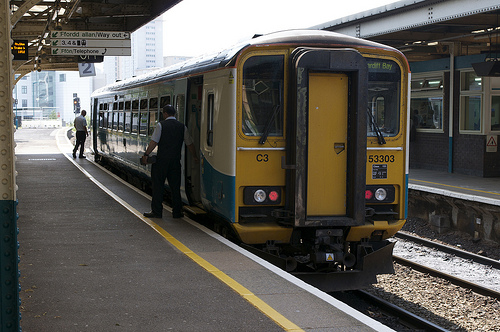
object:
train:
[90, 30, 407, 240]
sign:
[48, 24, 131, 55]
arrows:
[51, 31, 59, 39]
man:
[142, 103, 187, 225]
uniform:
[146, 119, 184, 222]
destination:
[363, 56, 398, 75]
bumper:
[262, 226, 398, 294]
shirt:
[160, 118, 183, 158]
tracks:
[345, 281, 443, 330]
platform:
[11, 3, 496, 331]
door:
[308, 70, 353, 218]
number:
[365, 154, 391, 162]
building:
[0, 0, 176, 331]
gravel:
[416, 279, 458, 305]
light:
[266, 188, 280, 201]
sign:
[252, 152, 271, 162]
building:
[29, 68, 57, 125]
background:
[12, 0, 219, 117]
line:
[179, 239, 221, 278]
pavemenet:
[20, 123, 230, 331]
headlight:
[251, 188, 266, 202]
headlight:
[376, 188, 386, 201]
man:
[74, 109, 89, 160]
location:
[58, 46, 107, 55]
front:
[236, 37, 401, 244]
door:
[188, 79, 205, 205]